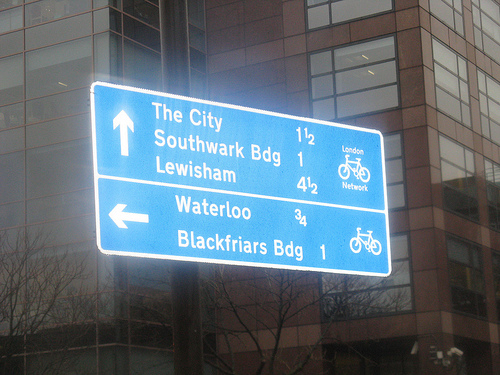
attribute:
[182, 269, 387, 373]
branches — no leaves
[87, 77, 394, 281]
street sign — green, white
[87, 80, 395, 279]
sign — blue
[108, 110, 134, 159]
arrow — white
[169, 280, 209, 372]
pole — black, white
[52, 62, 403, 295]
sign — green , off .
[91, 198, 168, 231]
arrow — large, white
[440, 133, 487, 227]
windows — black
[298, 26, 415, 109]
windows — outlined, black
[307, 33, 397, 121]
window — large, glass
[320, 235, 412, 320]
window — large, glass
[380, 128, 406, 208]
window — large, glass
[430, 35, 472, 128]
window — large, glass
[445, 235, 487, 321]
window — large, glass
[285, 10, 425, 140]
frame — brown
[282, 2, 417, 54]
frame — brown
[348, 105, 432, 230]
frame — brown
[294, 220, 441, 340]
frame — brown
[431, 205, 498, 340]
frame — brown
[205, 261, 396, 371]
trees — bare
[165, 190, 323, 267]
writing — white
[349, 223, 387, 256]
symbol — bike  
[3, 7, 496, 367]
building — large, brown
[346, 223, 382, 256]
symbol — bike